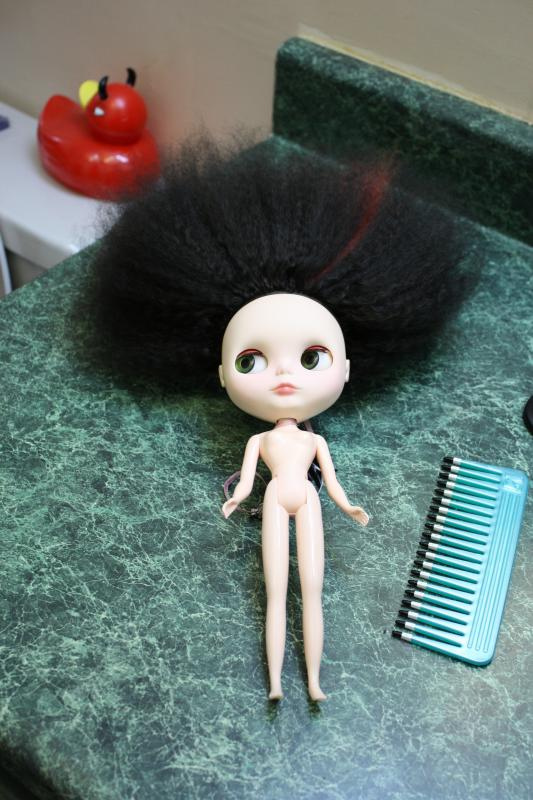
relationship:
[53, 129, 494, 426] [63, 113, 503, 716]
hair on doll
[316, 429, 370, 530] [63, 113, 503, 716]
arm on doll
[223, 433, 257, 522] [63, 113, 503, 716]
arm on doll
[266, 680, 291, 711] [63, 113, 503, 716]
feet on doll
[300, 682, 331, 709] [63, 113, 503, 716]
feet on doll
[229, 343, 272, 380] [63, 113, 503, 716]
eyes on doll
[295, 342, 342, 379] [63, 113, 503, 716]
eyes on doll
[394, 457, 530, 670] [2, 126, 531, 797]
comb on counter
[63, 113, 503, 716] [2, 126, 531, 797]
doll on counter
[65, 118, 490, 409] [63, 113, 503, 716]
hair on doll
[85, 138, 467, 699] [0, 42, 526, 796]
doll on counter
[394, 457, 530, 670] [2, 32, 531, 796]
comb on counter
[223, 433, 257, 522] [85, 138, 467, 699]
arm of doll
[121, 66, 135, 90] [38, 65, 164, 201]
horn of duck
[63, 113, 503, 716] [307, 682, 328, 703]
doll has feet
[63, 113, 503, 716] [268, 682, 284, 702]
doll has feet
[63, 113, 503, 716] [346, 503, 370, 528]
doll has hand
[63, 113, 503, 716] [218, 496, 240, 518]
doll has hand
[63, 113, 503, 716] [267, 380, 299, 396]
doll has mouth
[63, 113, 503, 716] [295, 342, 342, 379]
doll has eyes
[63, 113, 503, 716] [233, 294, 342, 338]
doll has forehead